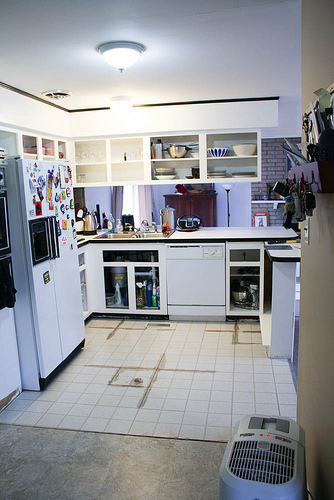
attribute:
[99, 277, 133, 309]
bottle — white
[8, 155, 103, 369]
refrigerator — large, white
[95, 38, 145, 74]
light — globe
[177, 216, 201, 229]
radio — small, black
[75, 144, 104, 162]
glassware — clear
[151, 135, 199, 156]
appliances — small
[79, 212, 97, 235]
coffeepot — stainless steel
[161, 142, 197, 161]
bowl — silver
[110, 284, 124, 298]
soap — in the picture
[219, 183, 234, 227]
lamp — in the picture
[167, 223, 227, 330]
dishwasher — white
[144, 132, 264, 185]
cabinet — kitchen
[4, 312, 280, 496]
floor — white, tile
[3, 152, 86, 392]
refrigerator — white, side by side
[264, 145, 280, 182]
wall — white, brick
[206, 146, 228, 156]
bowl — blue, white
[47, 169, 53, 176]
clip — blue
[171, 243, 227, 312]
dishwasher — in the picture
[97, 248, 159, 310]
cabinet — doorless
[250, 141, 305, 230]
wall — brick